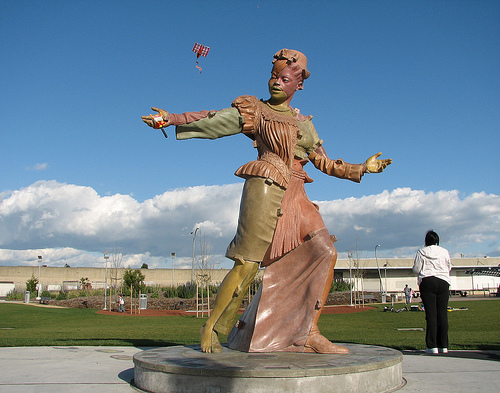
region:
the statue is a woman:
[160, 52, 383, 344]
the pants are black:
[416, 279, 463, 346]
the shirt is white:
[412, 245, 457, 279]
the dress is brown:
[223, 188, 288, 265]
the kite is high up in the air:
[188, 42, 217, 69]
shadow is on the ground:
[118, 332, 182, 352]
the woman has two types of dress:
[220, 178, 353, 359]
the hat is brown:
[273, 43, 308, 70]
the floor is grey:
[432, 362, 485, 392]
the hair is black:
[421, 232, 443, 244]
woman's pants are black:
[415, 271, 462, 357]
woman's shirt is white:
[408, 241, 450, 286]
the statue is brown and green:
[132, 28, 369, 363]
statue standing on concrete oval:
[100, 4, 420, 386]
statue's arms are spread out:
[110, 15, 395, 226]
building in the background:
[2, 240, 497, 315]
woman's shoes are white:
[417, 337, 457, 357]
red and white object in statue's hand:
[147, 106, 177, 146]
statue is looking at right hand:
[259, 38, 318, 108]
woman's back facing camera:
[408, 214, 473, 361]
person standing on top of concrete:
[411, 228, 453, 353]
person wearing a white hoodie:
[411, 229, 456, 354]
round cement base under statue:
[131, 338, 405, 391]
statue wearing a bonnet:
[268, 48, 310, 80]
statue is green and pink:
[141, 48, 398, 356]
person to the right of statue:
[410, 228, 455, 355]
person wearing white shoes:
[430, 348, 449, 351]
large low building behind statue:
[1, 263, 241, 303]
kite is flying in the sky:
[190, 41, 211, 73]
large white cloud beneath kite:
[1, 178, 237, 263]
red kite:
[173, 12, 231, 81]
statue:
[121, 43, 388, 355]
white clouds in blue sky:
[23, 30, 117, 108]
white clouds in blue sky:
[7, 173, 71, 206]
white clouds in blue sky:
[78, 175, 124, 221]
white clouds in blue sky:
[124, 152, 168, 202]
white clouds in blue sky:
[392, 175, 427, 201]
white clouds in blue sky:
[335, 196, 386, 254]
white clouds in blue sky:
[398, 35, 444, 90]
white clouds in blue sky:
[328, 52, 363, 96]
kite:
[166, 33, 208, 66]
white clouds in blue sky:
[37, 32, 81, 60]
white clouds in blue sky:
[34, 71, 95, 110]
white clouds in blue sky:
[31, 195, 94, 245]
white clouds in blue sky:
[99, 186, 140, 216]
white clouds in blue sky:
[161, 170, 216, 217]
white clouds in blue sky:
[351, 200, 374, 230]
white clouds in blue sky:
[439, 146, 478, 207]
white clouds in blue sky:
[355, 35, 413, 82]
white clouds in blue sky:
[402, 100, 457, 128]